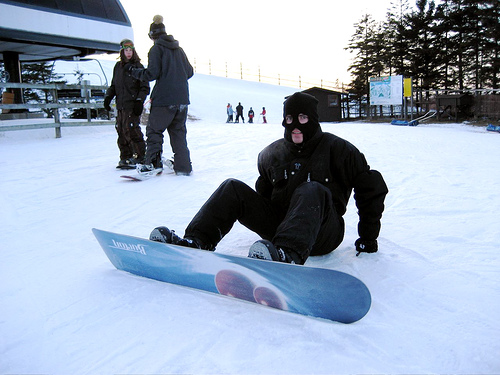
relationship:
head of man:
[279, 94, 326, 142] [146, 91, 386, 265]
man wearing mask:
[146, 91, 386, 265] [272, 85, 329, 155]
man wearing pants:
[146, 91, 386, 265] [185, 175, 346, 261]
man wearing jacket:
[156, 82, 401, 307] [253, 132, 393, 243]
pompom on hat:
[152, 14, 163, 25] [149, 13, 165, 39]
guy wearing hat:
[126, 15, 194, 175] [149, 13, 165, 39]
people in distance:
[222, 101, 270, 122] [4, 3, 484, 136]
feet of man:
[144, 220, 214, 260] [146, 91, 386, 265]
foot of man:
[246, 235, 283, 267] [146, 91, 386, 265]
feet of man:
[144, 226, 217, 250] [146, 91, 386, 265]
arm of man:
[344, 150, 389, 257] [146, 91, 386, 265]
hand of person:
[351, 235, 386, 257] [193, 68, 374, 249]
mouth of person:
[285, 125, 307, 139] [146, 100, 403, 263]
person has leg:
[103, 37, 151, 167] [112, 108, 134, 168]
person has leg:
[103, 37, 151, 167] [124, 110, 146, 163]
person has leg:
[121, 14, 197, 178] [143, 104, 172, 165]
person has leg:
[121, 14, 197, 178] [169, 110, 195, 175]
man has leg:
[146, 91, 386, 265] [184, 175, 280, 251]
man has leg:
[146, 91, 386, 265] [268, 182, 344, 266]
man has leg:
[146, 91, 386, 265] [249, 183, 344, 263]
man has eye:
[146, 91, 386, 265] [296, 112, 308, 122]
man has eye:
[146, 91, 386, 265] [284, 113, 293, 125]